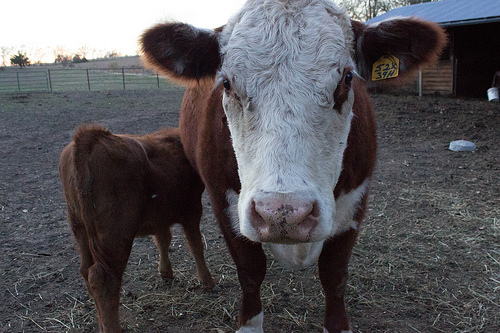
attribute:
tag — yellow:
[371, 59, 400, 78]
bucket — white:
[483, 87, 499, 106]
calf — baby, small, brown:
[65, 116, 216, 332]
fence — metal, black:
[3, 65, 185, 93]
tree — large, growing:
[13, 53, 27, 67]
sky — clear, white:
[0, 0, 394, 65]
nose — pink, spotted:
[248, 188, 323, 240]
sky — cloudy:
[44, 2, 129, 32]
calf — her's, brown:
[54, 124, 216, 329]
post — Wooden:
[414, 70, 426, 97]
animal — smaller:
[47, 123, 215, 330]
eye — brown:
[330, 58, 362, 99]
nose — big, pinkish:
[242, 191, 331, 245]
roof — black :
[370, 5, 498, 19]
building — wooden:
[358, 4, 498, 108]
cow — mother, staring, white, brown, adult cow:
[135, 0, 450, 327]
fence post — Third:
[83, 67, 90, 88]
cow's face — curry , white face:
[215, 2, 360, 245]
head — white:
[139, 5, 449, 246]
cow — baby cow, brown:
[55, 128, 220, 331]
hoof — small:
[218, 296, 250, 330]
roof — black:
[336, 9, 498, 43]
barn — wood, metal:
[361, 0, 496, 101]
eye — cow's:
[216, 76, 235, 99]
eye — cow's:
[337, 66, 356, 105]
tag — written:
[371, 56, 402, 80]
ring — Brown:
[332, 65, 355, 115]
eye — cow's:
[340, 74, 351, 95]